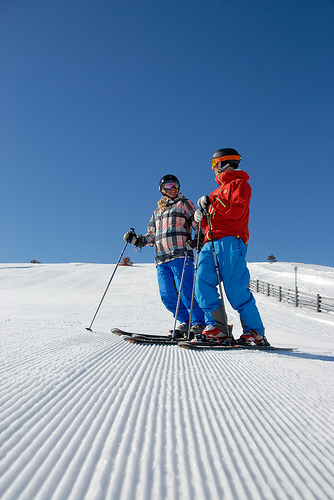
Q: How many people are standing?
A: 2.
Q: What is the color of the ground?
A: White.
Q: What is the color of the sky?
A: Blue.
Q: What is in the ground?
A: Snow.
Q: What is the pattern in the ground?
A: Ridge pattern.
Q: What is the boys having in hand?
A: Ski poles.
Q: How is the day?
A: Sunny.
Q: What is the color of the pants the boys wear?
A: Blue.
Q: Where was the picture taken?
A: On a ski slope.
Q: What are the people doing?
A: Skiing.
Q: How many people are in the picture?
A: 2.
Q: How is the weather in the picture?
A: Sunny.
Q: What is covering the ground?
A: Snow.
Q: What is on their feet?
A: Skis.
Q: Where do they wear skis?
A: The snow.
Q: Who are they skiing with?
A: Each other.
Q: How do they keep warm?
A: Snow suits.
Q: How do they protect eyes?
A: Goggles.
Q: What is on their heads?
A: Helmets.